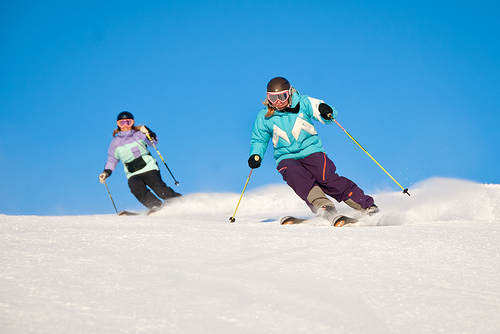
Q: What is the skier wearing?
A: A black helmet.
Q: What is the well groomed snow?
A: On the ski run.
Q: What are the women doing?
A: Skiing.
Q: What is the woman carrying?
A: Ski poles.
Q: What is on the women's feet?
A: Skis.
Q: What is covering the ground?
A: Snow.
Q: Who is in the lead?
A: Woman on right.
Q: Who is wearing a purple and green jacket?
A: Woman on left.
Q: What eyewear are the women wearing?
A: Goggles.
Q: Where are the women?
A: Ski slope.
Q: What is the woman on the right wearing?
A: Purple pants.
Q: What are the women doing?
A: Skiing.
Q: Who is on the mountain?
A: Skiers.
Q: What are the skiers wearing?
A: Jackets.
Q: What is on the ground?
A: Snow.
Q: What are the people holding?
A: Poles.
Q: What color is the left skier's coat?
A: Purple, blue and black.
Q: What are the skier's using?
A: Ski sticks.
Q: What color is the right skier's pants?
A: Purple and red.